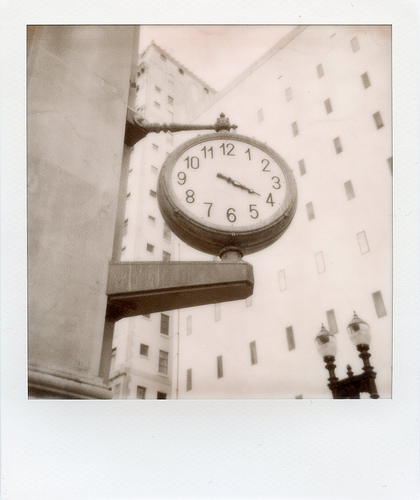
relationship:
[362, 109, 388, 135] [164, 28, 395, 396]
window on building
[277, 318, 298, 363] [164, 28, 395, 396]
window on building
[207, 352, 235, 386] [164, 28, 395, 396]
window on building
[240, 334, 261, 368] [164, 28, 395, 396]
window on building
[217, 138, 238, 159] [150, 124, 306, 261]
number on clock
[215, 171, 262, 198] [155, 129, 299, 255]
hand on clock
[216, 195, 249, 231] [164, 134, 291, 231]
6 on clock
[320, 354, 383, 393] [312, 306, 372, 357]
posts holding lamps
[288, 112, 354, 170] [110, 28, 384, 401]
window on building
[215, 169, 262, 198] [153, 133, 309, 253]
hand on clock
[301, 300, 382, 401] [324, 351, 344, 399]
lamp on pole